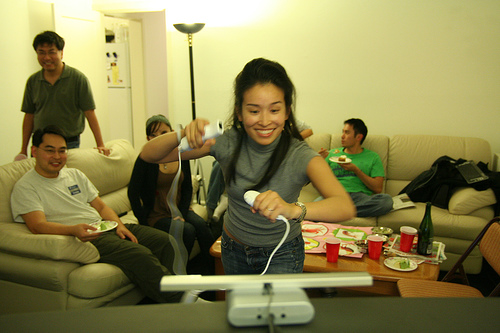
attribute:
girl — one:
[210, 57, 355, 316]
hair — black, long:
[230, 49, 295, 168]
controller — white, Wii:
[240, 184, 281, 222]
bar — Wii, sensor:
[160, 263, 375, 288]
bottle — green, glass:
[410, 201, 437, 266]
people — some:
[13, 108, 368, 258]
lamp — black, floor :
[170, 18, 215, 122]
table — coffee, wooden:
[300, 214, 441, 282]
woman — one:
[200, 45, 336, 263]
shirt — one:
[216, 135, 303, 250]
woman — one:
[215, 56, 311, 275]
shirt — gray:
[213, 132, 315, 255]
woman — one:
[201, 56, 307, 269]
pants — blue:
[213, 230, 303, 270]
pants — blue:
[219, 234, 306, 271]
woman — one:
[218, 59, 318, 267]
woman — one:
[218, 54, 313, 255]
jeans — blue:
[225, 218, 318, 288]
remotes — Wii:
[155, 109, 300, 231]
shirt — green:
[340, 150, 373, 188]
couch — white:
[354, 68, 454, 246]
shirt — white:
[21, 172, 111, 232]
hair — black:
[42, 31, 92, 56]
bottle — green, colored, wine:
[408, 194, 442, 249]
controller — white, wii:
[173, 120, 215, 162]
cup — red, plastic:
[304, 220, 344, 271]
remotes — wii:
[157, 104, 275, 230]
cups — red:
[290, 204, 410, 286]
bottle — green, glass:
[389, 186, 435, 264]